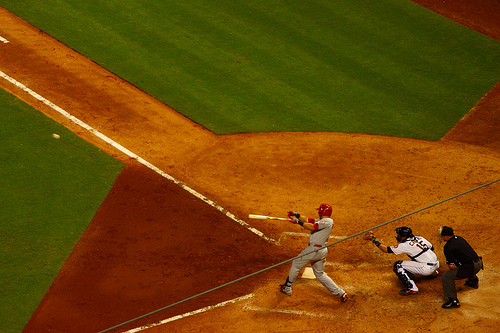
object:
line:
[203, 190, 278, 249]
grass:
[0, 147, 53, 259]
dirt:
[106, 109, 147, 138]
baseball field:
[0, 0, 466, 325]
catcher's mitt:
[361, 230, 378, 241]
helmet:
[316, 203, 333, 218]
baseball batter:
[278, 202, 349, 301]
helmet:
[393, 226, 415, 243]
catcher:
[362, 226, 441, 298]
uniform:
[282, 218, 344, 296]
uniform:
[387, 235, 440, 292]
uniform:
[439, 234, 487, 299]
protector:
[392, 267, 409, 283]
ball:
[52, 133, 61, 141]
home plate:
[300, 266, 316, 280]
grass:
[176, 0, 459, 181]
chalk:
[112, 280, 301, 318]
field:
[10, 10, 246, 226]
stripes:
[21, 80, 164, 177]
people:
[276, 203, 349, 303]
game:
[103, 70, 486, 321]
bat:
[249, 213, 293, 222]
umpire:
[435, 225, 485, 310]